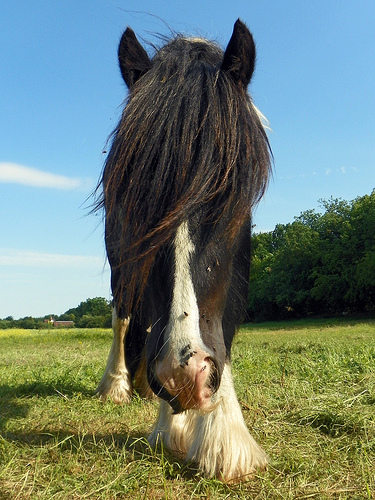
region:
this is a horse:
[84, 10, 309, 471]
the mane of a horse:
[83, 48, 267, 284]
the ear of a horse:
[224, 8, 266, 95]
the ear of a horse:
[101, 27, 157, 80]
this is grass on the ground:
[326, 386, 365, 464]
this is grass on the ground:
[289, 382, 351, 478]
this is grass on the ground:
[24, 399, 84, 472]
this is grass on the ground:
[28, 342, 101, 403]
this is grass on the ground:
[97, 471, 128, 487]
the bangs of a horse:
[80, 76, 281, 269]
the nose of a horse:
[141, 347, 226, 408]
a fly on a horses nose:
[178, 306, 197, 329]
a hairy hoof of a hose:
[189, 411, 270, 481]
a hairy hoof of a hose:
[97, 369, 133, 402]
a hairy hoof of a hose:
[145, 411, 188, 457]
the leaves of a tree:
[301, 239, 352, 279]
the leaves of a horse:
[81, 301, 112, 328]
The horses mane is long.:
[85, 76, 265, 307]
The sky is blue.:
[10, 192, 60, 226]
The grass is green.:
[289, 371, 365, 446]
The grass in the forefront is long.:
[289, 394, 366, 463]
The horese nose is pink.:
[142, 356, 217, 402]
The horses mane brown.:
[78, 46, 285, 320]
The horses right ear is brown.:
[110, 25, 152, 85]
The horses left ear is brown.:
[219, 15, 261, 83]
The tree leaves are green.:
[305, 229, 369, 291]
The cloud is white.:
[1, 158, 80, 195]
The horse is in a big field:
[51, 33, 293, 487]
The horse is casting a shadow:
[0, 9, 330, 479]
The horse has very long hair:
[41, 20, 328, 488]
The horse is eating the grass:
[45, 20, 306, 488]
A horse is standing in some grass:
[60, 13, 319, 487]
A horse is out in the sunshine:
[63, 17, 267, 497]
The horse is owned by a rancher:
[45, 12, 350, 492]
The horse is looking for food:
[71, 9, 286, 489]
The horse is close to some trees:
[53, 10, 305, 491]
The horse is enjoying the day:
[62, 7, 352, 499]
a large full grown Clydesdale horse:
[61, 17, 291, 483]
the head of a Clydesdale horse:
[93, 31, 259, 411]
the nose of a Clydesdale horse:
[146, 346, 223, 410]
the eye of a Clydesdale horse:
[215, 204, 250, 216]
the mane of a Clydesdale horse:
[133, 92, 234, 194]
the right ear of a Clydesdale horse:
[101, 28, 150, 85]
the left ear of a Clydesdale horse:
[216, 14, 267, 90]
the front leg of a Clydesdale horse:
[139, 400, 263, 481]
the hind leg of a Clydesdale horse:
[95, 303, 134, 398]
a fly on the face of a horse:
[169, 299, 208, 339]